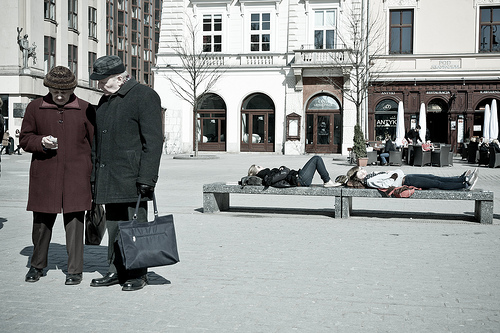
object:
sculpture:
[15, 25, 38, 69]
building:
[4, 0, 159, 157]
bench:
[200, 181, 493, 225]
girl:
[248, 156, 344, 188]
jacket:
[256, 166, 299, 188]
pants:
[402, 173, 465, 189]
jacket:
[363, 169, 406, 189]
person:
[379, 135, 394, 166]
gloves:
[137, 181, 154, 199]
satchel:
[116, 193, 180, 270]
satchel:
[82, 199, 108, 246]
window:
[386, 6, 415, 56]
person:
[87, 56, 165, 292]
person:
[18, 65, 96, 285]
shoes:
[25, 265, 44, 282]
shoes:
[65, 272, 82, 285]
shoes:
[122, 276, 147, 292]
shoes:
[90, 271, 124, 286]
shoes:
[323, 180, 341, 188]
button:
[102, 129, 108, 134]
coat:
[93, 75, 163, 205]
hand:
[42, 135, 59, 150]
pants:
[32, 209, 84, 275]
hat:
[89, 55, 124, 80]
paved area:
[0, 150, 499, 332]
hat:
[43, 65, 77, 90]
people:
[335, 165, 480, 188]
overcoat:
[20, 91, 96, 215]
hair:
[334, 166, 362, 188]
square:
[0, 150, 499, 332]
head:
[89, 55, 131, 97]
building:
[359, 0, 500, 168]